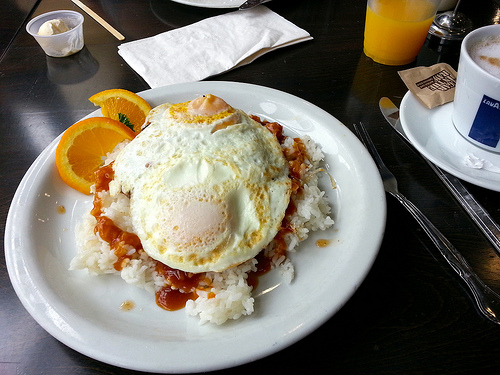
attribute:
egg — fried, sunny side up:
[113, 93, 290, 192]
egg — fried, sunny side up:
[130, 147, 293, 272]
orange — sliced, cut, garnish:
[56, 115, 139, 195]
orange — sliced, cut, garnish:
[89, 87, 152, 136]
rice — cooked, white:
[70, 115, 337, 324]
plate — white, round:
[2, 80, 388, 373]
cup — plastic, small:
[26, 9, 85, 60]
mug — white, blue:
[454, 25, 500, 153]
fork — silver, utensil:
[350, 119, 499, 323]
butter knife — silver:
[377, 96, 500, 246]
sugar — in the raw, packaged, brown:
[396, 62, 460, 110]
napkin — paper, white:
[117, 5, 312, 90]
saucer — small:
[397, 87, 497, 190]